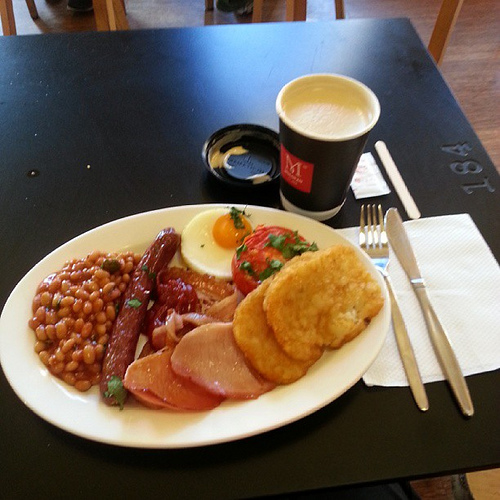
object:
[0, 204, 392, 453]
plate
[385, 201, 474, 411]
knife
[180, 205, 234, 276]
egg white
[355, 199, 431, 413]
fork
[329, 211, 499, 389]
napkin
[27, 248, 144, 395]
beans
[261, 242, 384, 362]
hash brown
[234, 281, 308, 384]
hash brown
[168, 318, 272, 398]
ham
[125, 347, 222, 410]
ham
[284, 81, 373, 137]
coffee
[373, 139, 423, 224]
stick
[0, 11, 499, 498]
table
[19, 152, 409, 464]
plate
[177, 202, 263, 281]
egg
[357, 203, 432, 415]
fork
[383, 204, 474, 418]
butter knife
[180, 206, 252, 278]
egg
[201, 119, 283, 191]
lid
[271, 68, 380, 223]
cup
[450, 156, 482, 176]
8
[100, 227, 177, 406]
sausage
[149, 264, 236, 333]
bacon